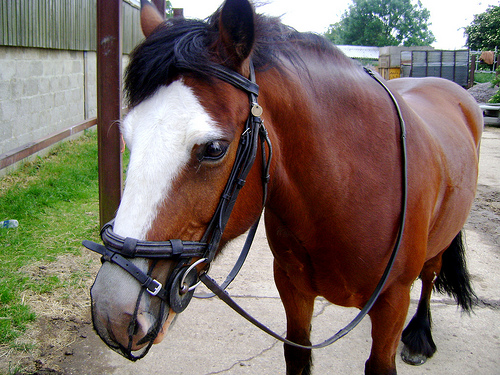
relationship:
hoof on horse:
[396, 285, 441, 368] [68, 2, 495, 372]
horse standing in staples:
[68, 2, 495, 372] [180, 332, 232, 374]